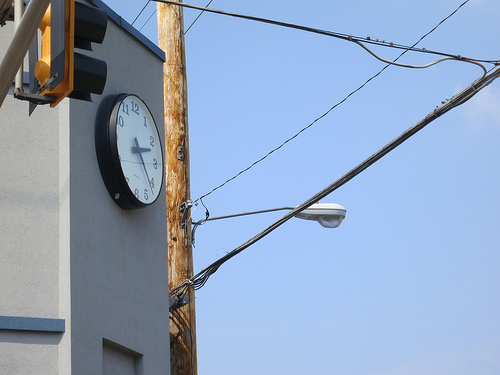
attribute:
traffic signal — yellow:
[19, 5, 107, 103]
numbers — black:
[115, 92, 145, 119]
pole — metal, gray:
[0, 0, 53, 116]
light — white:
[291, 200, 350, 230]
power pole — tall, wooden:
[164, 2, 192, 373]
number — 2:
[147, 132, 156, 149]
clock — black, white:
[95, 74, 180, 242]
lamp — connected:
[199, 196, 353, 238]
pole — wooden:
[152, 1, 204, 373]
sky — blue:
[103, 2, 497, 373]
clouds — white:
[372, 208, 477, 313]